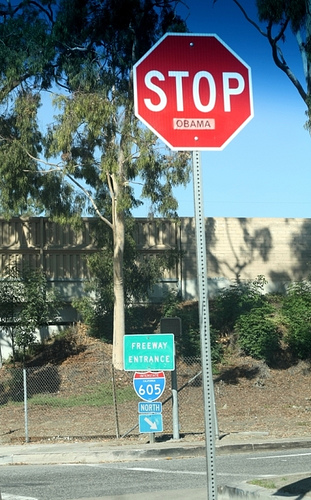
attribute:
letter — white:
[142, 58, 248, 116]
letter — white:
[138, 63, 172, 119]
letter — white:
[166, 67, 194, 117]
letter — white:
[191, 66, 223, 117]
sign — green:
[118, 329, 183, 376]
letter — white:
[217, 64, 251, 119]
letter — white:
[129, 340, 147, 354]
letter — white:
[145, 340, 156, 351]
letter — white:
[136, 381, 150, 400]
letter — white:
[141, 352, 155, 366]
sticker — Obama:
[170, 115, 220, 132]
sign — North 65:
[130, 371, 170, 403]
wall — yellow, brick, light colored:
[5, 216, 304, 299]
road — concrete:
[8, 450, 310, 495]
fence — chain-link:
[12, 366, 129, 440]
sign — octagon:
[123, 24, 263, 155]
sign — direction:
[134, 410, 171, 433]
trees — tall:
[3, 6, 135, 290]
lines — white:
[65, 458, 240, 481]